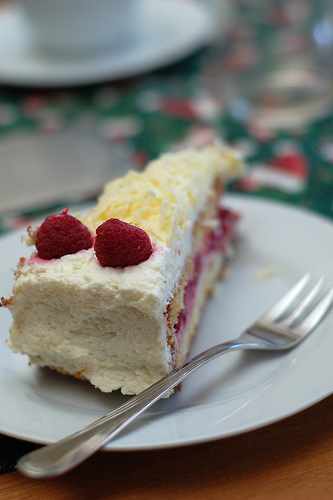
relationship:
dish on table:
[1, 188, 333, 451] [1, 2, 331, 499]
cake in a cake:
[5, 146, 236, 395] [5, 146, 243, 400]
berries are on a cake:
[38, 216, 153, 268] [5, 146, 236, 395]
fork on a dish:
[13, 272, 331, 480] [1, 188, 333, 451]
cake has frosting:
[5, 146, 236, 395] [9, 250, 184, 405]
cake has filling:
[5, 146, 236, 395] [166, 223, 234, 344]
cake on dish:
[5, 146, 236, 395] [1, 188, 333, 451]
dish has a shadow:
[1, 188, 333, 451] [1, 296, 329, 484]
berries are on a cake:
[38, 216, 153, 268] [5, 146, 243, 400]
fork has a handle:
[13, 272, 331, 480] [18, 339, 226, 481]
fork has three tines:
[13, 272, 331, 480] [272, 273, 332, 335]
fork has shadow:
[13, 272, 331, 480] [131, 339, 284, 428]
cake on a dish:
[5, 146, 236, 395] [1, 188, 333, 451]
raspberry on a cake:
[35, 211, 93, 261] [5, 146, 243, 400]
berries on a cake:
[92, 216, 152, 268] [5, 146, 243, 400]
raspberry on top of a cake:
[35, 211, 93, 261] [5, 146, 243, 400]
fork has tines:
[13, 272, 331, 480] [272, 273, 332, 335]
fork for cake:
[13, 272, 331, 480] [5, 146, 243, 400]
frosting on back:
[9, 250, 184, 405] [6, 279, 171, 398]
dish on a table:
[1, 188, 333, 451] [1, 2, 331, 499]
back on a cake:
[6, 279, 171, 398] [5, 146, 243, 400]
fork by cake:
[13, 272, 331, 480] [5, 146, 243, 400]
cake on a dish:
[5, 146, 243, 400] [1, 188, 333, 451]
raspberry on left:
[35, 211, 93, 261] [15, 180, 91, 376]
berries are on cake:
[38, 216, 153, 268] [5, 146, 236, 395]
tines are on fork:
[272, 273, 332, 335] [13, 272, 331, 480]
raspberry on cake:
[35, 211, 93, 261] [5, 146, 236, 395]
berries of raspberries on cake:
[92, 216, 152, 268] [5, 146, 236, 395]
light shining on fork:
[272, 270, 332, 346] [13, 272, 331, 480]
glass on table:
[207, 1, 332, 124] [1, 2, 331, 499]